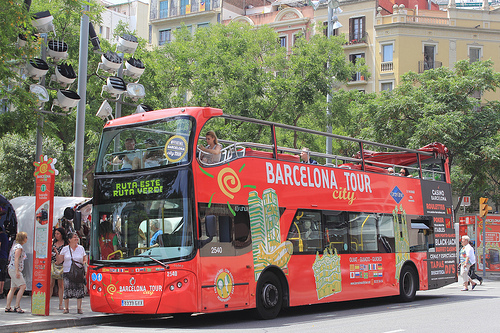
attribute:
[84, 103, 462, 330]
bus — double decker, red, black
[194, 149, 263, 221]
picture of sun — graphic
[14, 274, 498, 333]
street — shining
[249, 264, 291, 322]
wheel — black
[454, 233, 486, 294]
woman — walking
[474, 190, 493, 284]
traffic light — yellow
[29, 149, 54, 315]
sign — tall, red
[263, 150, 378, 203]
words — white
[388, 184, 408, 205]
logo — blue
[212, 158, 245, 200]
sun — yellow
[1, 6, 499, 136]
trees — leafy